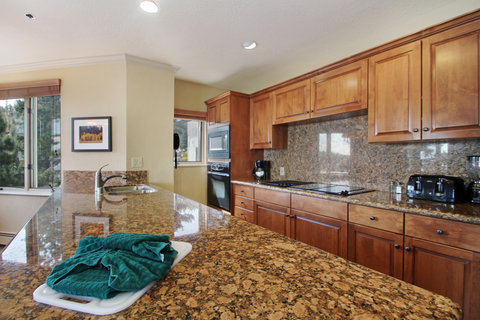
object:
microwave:
[206, 124, 230, 158]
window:
[0, 85, 62, 189]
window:
[173, 118, 202, 161]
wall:
[61, 60, 127, 182]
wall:
[126, 60, 175, 193]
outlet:
[131, 156, 143, 167]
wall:
[61, 54, 176, 193]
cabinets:
[249, 9, 479, 150]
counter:
[0, 184, 444, 317]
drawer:
[233, 183, 254, 198]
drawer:
[235, 195, 253, 211]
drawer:
[234, 206, 255, 223]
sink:
[287, 183, 375, 196]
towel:
[46, 232, 178, 299]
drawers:
[234, 184, 254, 223]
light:
[140, 0, 159, 13]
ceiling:
[0, 0, 383, 84]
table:
[197, 227, 251, 290]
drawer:
[349, 204, 403, 234]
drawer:
[405, 214, 480, 253]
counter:
[230, 180, 480, 224]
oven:
[207, 161, 231, 210]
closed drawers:
[348, 204, 480, 252]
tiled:
[112, 200, 194, 232]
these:
[233, 184, 461, 224]